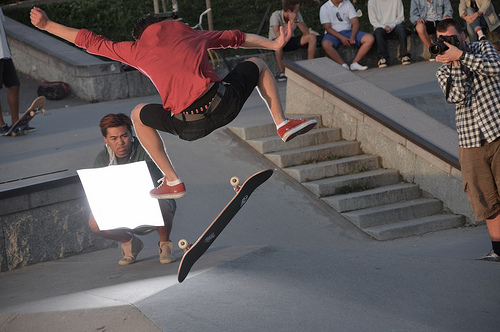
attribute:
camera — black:
[427, 34, 457, 59]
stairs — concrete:
[227, 112, 464, 239]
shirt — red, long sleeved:
[70, 19, 248, 115]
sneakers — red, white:
[269, 113, 331, 150]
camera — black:
[415, 19, 498, 234]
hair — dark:
[432, 12, 481, 37]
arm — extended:
[27, 6, 134, 63]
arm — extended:
[194, 18, 294, 50]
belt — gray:
[160, 74, 231, 123]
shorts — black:
[137, 57, 264, 145]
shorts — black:
[456, 134, 499, 226]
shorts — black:
[268, 30, 304, 51]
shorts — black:
[323, 29, 368, 47]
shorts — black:
[414, 16, 440, 37]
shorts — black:
[1, 55, 21, 94]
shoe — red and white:
[270, 115, 321, 142]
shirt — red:
[65, 14, 237, 91]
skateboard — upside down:
[174, 162, 280, 281]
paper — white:
[71, 157, 171, 238]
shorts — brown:
[456, 144, 497, 218]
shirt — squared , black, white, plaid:
[434, 39, 496, 148]